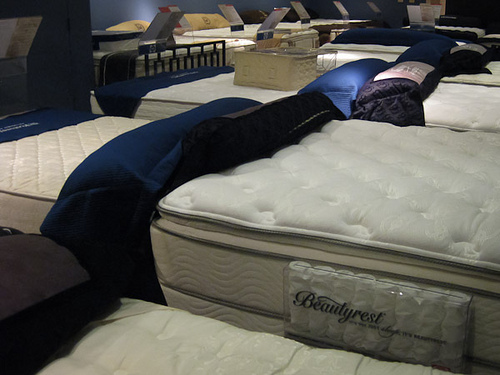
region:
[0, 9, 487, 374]
Mattress showroom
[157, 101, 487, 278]
pillow topped mattress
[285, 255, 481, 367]
manufacturer name and sample of inner coils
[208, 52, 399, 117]
navy blue body pillows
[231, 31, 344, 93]
sample shows inside construction of mattress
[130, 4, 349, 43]
signs telling specifications of mattresses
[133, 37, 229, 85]
a base board of a bed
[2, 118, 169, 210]
a mattress without a pillow top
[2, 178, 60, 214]
piping around seam of mattress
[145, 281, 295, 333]
a box spring under mattress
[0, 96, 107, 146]
blue cover on mattress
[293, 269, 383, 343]
black letters on mattress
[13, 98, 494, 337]
the mattress is white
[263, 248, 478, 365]
plastic on side of mattress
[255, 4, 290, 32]
sign in front of mattress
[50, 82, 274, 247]
blue cover on mattress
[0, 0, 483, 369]
scene takes place in mattress store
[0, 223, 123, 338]
the pillow is gray and black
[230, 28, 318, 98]
white stand near mattress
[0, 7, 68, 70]
sign in front of mattress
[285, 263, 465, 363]
The mattress says "beautry rest".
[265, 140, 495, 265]
The mattress is white.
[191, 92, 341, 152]
The pillow is black.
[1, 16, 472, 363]
This is in a bed store.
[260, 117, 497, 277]
This is a mattress.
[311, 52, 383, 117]
The pillow is blue.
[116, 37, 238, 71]
The bed frame is black.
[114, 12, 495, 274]
These mattresses are for sale.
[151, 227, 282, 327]
The pillowtop is white.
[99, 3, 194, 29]
The background wall is blue.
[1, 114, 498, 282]
a top of a padded mattress.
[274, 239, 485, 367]
a company logo on the side of a bead.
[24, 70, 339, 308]
a blanket on a bed.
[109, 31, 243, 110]
a foot board on a bed.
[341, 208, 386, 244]
a dip on a bed.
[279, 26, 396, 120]
a blue blanket.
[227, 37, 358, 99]
a box on a bed.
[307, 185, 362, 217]
a dimple on a bed.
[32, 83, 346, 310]
a dark blanket.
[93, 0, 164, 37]
a section of a dark blue wall.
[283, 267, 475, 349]
advertisement label on mattress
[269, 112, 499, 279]
quilted top of mattress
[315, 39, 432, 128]
a pair of blankets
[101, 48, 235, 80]
black metal foot board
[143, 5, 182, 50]
sign with details of mattress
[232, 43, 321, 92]
a woven wicker basket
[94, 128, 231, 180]
a dark blue blanket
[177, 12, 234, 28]
long mustard yellow pillow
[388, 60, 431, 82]
pink printed fabric on blanket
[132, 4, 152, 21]
pale blue wall behind bed